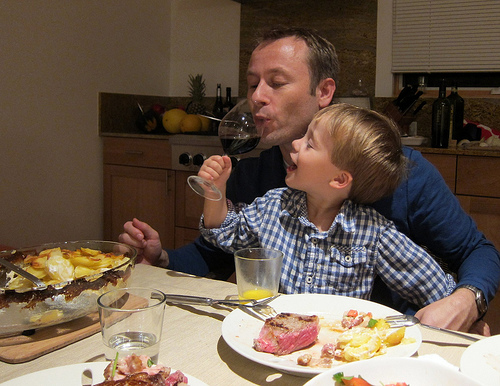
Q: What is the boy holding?
A: A wine glass.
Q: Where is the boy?
A: In the man's lap.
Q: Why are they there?
A: It is time for dinner.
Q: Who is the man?
A: The boy's father.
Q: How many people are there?
A: Two.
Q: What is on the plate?
A: Meat and potatoes.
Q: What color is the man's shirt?
A: Blue.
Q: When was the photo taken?
A: During the day.